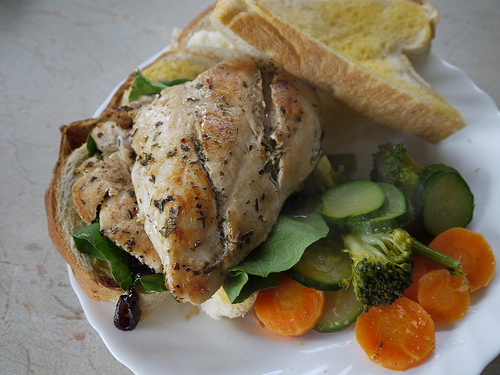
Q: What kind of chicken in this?
A: Grilled.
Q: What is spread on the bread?
A: Mustard.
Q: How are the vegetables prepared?
A: Steamed.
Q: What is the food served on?
A: Plate.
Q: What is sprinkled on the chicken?
A: Herbs.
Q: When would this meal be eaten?
A: Lunch.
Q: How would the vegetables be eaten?
A: With a fork.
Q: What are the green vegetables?
A: Broccoli and zucchini.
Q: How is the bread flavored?
A: Buttered.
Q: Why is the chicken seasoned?
A: To taste good.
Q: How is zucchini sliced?
A: Thinly.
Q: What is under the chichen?
A: Lettuce and bread.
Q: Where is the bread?
A: Beneath chicken.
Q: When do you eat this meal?
A: Lunch or dinner.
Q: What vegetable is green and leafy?
A: Lettuce.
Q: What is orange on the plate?
A: Carrots.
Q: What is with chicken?
A: Bread.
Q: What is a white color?
A: A plate.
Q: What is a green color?
A: A cucumber.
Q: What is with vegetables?
A: Chicken sandwich.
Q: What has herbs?
A: Chicken.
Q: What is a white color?
A: A plate.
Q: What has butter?
A: The bread.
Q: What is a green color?
A: The lettuce.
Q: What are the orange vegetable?
A: Carrots.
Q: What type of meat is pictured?
A: Chicken.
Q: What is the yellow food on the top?
A: Bread.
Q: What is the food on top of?
A: Plate.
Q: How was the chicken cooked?
A: Grilled.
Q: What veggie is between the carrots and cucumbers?
A: Broccoli.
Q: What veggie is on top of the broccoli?
A: Cucumber.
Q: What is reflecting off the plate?
A: Light.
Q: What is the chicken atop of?
A: Bread.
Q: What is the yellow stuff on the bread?
A: Butter.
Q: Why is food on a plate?
A: To be eaten.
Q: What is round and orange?
A: Carrot slices.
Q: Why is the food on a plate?
A: To eat.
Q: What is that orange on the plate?
A: That is carrot.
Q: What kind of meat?
A: Chicken breast.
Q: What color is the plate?
A: Its white.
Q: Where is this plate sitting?
A: On the table.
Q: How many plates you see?
A: Only one.